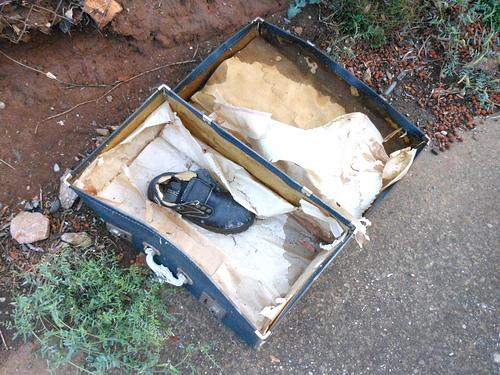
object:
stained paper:
[191, 38, 405, 154]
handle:
[141, 241, 194, 289]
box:
[172, 15, 430, 223]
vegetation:
[0, 247, 213, 375]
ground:
[0, 0, 500, 374]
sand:
[3, 2, 315, 214]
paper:
[209, 97, 417, 223]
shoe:
[147, 168, 256, 235]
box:
[63, 84, 356, 350]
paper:
[73, 101, 345, 330]